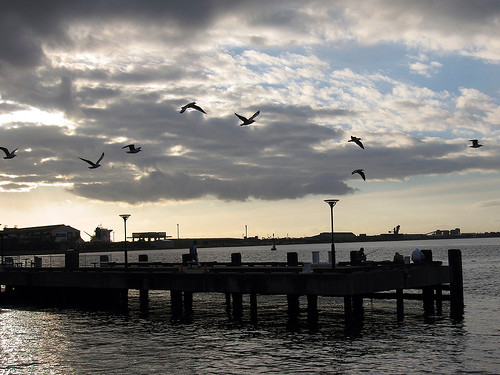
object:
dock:
[1, 247, 465, 332]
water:
[1, 345, 63, 375]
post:
[124, 221, 128, 272]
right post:
[331, 205, 336, 270]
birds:
[348, 135, 365, 150]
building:
[0, 223, 80, 242]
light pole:
[177, 223, 180, 240]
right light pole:
[245, 225, 247, 241]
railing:
[0, 251, 114, 271]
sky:
[1, 1, 500, 176]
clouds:
[460, 1, 499, 31]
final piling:
[446, 246, 463, 311]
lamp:
[119, 214, 131, 221]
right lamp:
[323, 199, 340, 207]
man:
[357, 247, 367, 264]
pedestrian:
[189, 241, 201, 269]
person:
[411, 248, 424, 265]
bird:
[0, 145, 20, 160]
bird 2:
[78, 152, 104, 170]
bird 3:
[120, 141, 142, 156]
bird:
[179, 101, 207, 114]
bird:
[347, 136, 365, 150]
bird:
[352, 168, 366, 181]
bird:
[468, 139, 483, 149]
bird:
[233, 108, 262, 127]